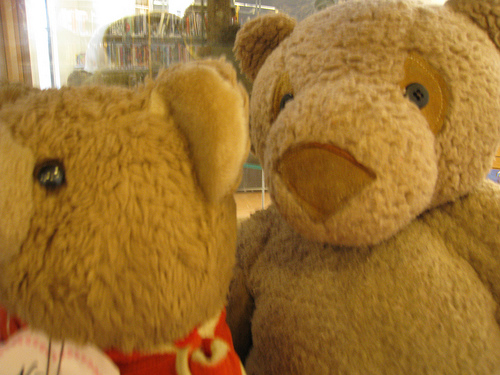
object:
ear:
[229, 11, 290, 74]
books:
[141, 9, 149, 39]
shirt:
[0, 303, 248, 374]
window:
[4, 0, 344, 191]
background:
[0, 0, 499, 220]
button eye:
[402, 81, 432, 113]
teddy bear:
[224, 2, 499, 373]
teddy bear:
[0, 57, 251, 372]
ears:
[439, 0, 498, 48]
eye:
[277, 90, 297, 114]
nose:
[268, 134, 381, 226]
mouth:
[297, 210, 356, 241]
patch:
[0, 319, 129, 372]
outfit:
[2, 306, 253, 373]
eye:
[32, 150, 69, 194]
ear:
[148, 56, 252, 212]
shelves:
[99, 36, 207, 46]